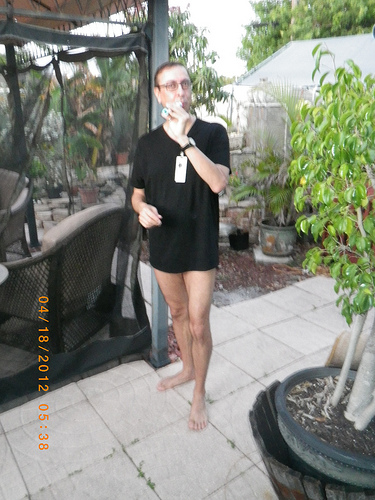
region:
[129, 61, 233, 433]
older man not wearing pants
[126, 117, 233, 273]
black v-neck t-shirt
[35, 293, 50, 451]
orange time and date stamp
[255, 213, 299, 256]
green plant pot with orange and white flower decoration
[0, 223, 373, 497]
patterned concrete paving stones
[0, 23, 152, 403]
black bug netting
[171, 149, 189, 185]
white i.d. badge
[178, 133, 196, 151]
watch with a black band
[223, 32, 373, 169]
white garden tent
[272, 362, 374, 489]
green pot sitting inside a wooden barrel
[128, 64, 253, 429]
man wearing no pants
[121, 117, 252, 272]
solid black tee shirt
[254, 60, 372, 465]
tree growing in a pot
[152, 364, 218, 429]
two bare feet on ground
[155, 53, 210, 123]
middle aged man wearing glasses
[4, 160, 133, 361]
two large wicker chairs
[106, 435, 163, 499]
grass growing through cracks in the floor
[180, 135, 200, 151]
black watch on left arm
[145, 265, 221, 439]
two bare legs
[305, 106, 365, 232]
green leaves on potted plant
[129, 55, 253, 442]
the man wearing the t shirt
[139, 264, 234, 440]
the man not wearing pants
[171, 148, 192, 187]
the id badge on the man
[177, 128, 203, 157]
the watch on the wrist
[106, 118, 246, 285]
the t shirt is black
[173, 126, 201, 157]
the watch is black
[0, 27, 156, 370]
the net attached to the awning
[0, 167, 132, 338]
the patio chair under the awning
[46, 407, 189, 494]
the concrete tiles on the ground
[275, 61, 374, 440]
the small tree beside the man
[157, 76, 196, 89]
A pair of glasses.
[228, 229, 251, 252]
A black flower pot.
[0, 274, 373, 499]
Light colored cement square blocks.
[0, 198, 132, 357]
A dark brown wicker chair.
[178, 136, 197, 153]
A black wristwatch.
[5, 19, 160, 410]
A screened in area.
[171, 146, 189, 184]
An identification badge.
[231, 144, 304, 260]
A potted plant.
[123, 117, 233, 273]
A black short sleeved shirt.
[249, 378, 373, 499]
A wooden barrel style flower pot.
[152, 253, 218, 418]
The man has no pants on.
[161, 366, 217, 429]
The man is not wearing shoes.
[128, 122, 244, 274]
The man is wearing a black shirt.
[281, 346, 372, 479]
The plant is in the pot.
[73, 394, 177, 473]
The flooring is tile.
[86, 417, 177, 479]
The tile is white in color.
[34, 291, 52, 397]
The date is 04/18/2012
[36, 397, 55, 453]
The time is 05:38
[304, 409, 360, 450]
The color of the dirt is black.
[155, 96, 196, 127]
The man is putting on chap stick.